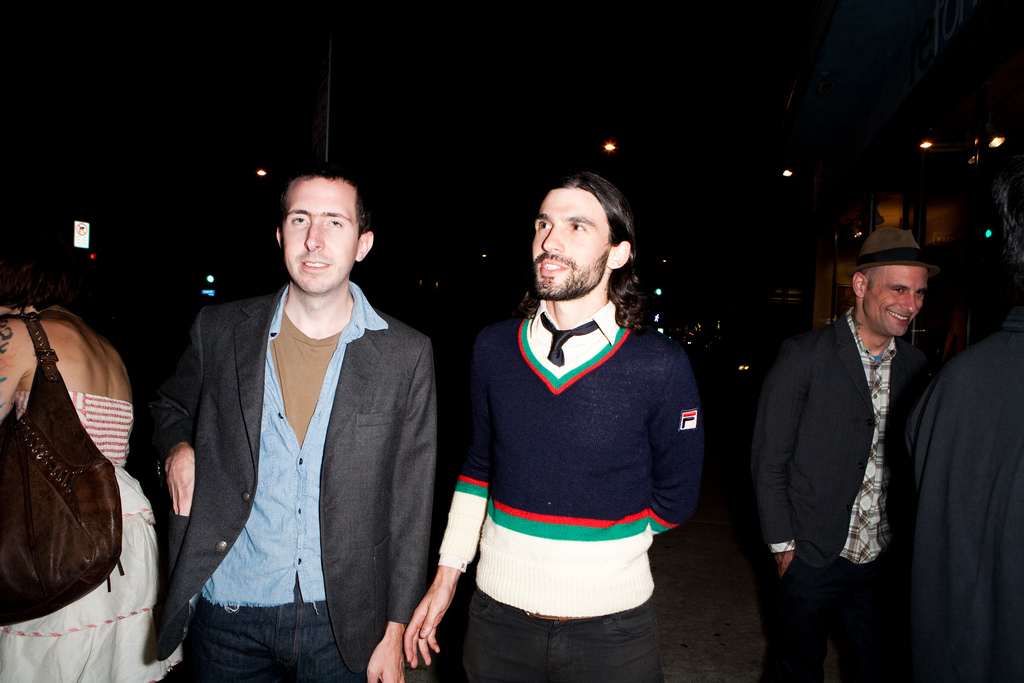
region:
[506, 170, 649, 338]
a man with long black hair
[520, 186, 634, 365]
a man wearing a neck tie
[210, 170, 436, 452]
a man wearing a brown tee shirt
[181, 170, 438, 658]
a man wearing a grey suit jacket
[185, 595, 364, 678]
a person wearing blue jeans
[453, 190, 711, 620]
a man wearing a striped sweater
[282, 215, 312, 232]
eye of the person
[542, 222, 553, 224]
eye of the person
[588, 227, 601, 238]
eye of the person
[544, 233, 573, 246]
nose of the man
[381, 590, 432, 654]
hand of the man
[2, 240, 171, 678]
person standing in the dark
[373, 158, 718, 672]
person standing in the dark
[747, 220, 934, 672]
person standing in the dark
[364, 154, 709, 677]
person standing in the dark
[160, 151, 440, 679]
person standing in the dark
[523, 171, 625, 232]
man has black hair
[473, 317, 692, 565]
man has blue shirt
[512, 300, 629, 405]
man has black tie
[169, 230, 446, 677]
man has light blue shirt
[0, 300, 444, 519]
man has grey coat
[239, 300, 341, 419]
man has brown undershirt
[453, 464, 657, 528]
green stripe on shirt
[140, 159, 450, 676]
A man wearing a dark grey blazer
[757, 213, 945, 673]
A man wearing a brown hat.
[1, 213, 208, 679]
A woman holding a brown shoulder bag.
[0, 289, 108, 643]
A brown shoulder bag.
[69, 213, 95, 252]
A street sign.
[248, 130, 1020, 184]
Lit up street lights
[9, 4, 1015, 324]
A black sky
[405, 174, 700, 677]
the man has short facial hair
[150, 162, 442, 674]
the man is wearing a gray jacket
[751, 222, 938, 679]
the man is wearing a brown hat